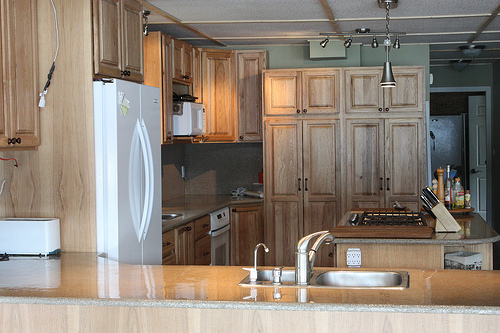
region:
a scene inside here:
[5, 5, 495, 315]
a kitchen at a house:
[5, 5, 495, 305]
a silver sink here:
[226, 220, 426, 305]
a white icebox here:
[75, 65, 172, 270]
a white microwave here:
[160, 91, 215, 141]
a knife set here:
[411, 182, 461, 237]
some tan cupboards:
[251, 55, 456, 262]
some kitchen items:
[417, 158, 489, 213]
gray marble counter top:
[0, 245, 497, 317]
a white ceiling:
[144, 0, 496, 62]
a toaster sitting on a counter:
[0, 213, 72, 270]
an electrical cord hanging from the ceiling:
[36, 0, 65, 117]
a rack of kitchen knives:
[419, 183, 475, 241]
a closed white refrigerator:
[90, 72, 176, 274]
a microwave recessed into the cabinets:
[170, 95, 212, 140]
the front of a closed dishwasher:
[205, 204, 237, 266]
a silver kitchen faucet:
[287, 208, 352, 301]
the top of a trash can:
[437, 247, 495, 278]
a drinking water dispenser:
[245, 232, 270, 293]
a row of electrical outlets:
[339, 240, 369, 272]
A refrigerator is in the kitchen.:
[80, 70, 180, 277]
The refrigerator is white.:
[83, 72, 178, 274]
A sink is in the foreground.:
[225, 225, 421, 305]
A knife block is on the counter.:
[415, 175, 462, 240]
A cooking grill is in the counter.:
[326, 196, 431, 232]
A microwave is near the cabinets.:
[156, 82, 218, 149]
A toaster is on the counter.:
[0, 196, 82, 262]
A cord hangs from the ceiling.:
[28, 0, 74, 123]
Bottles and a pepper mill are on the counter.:
[425, 155, 476, 215]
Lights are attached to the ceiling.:
[296, 15, 419, 101]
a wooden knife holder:
[431, 210, 459, 232]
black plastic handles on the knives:
[418, 190, 440, 205]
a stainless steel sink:
[331, 268, 391, 290]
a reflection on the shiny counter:
[113, 260, 198, 302]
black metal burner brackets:
[364, 212, 425, 231]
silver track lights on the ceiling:
[321, 33, 412, 53]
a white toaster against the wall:
[4, 208, 68, 262]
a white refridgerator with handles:
[112, 84, 170, 262]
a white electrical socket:
[341, 247, 371, 264]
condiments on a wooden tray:
[440, 165, 470, 207]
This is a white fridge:
[91, 81, 175, 262]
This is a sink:
[318, 268, 405, 298]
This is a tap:
[290, 232, 331, 297]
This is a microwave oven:
[177, 99, 212, 135]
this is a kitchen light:
[379, 38, 400, 100]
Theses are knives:
[417, 183, 449, 235]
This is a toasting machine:
[3, 218, 59, 256]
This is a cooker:
[208, 212, 229, 264]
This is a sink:
[256, 266, 294, 286]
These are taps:
[253, 243, 280, 288]